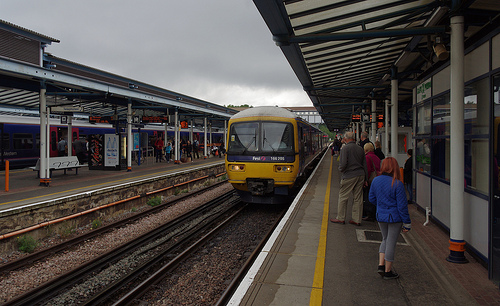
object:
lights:
[231, 161, 293, 176]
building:
[253, 0, 498, 302]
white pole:
[448, 15, 466, 262]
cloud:
[195, 82, 267, 102]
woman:
[362, 142, 382, 189]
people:
[326, 118, 411, 283]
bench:
[28, 153, 91, 180]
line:
[306, 153, 333, 304]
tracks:
[0, 175, 293, 304]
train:
[217, 96, 304, 211]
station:
[0, 9, 497, 304]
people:
[136, 129, 224, 160]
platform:
[7, 136, 227, 225]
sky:
[36, 0, 313, 117]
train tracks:
[156, 197, 250, 303]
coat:
[369, 174, 411, 224]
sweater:
[332, 140, 367, 176]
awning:
[6, 60, 246, 131]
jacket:
[362, 150, 380, 174]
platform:
[213, 139, 476, 291]